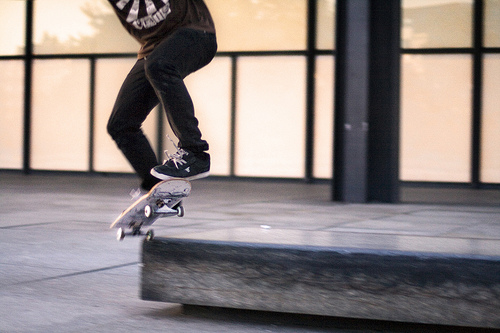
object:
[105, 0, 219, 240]
skateboarder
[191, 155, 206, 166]
black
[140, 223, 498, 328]
bench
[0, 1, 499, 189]
building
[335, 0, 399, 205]
pole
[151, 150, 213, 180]
foot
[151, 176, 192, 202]
front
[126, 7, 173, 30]
writing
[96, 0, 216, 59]
shirt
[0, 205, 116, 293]
ground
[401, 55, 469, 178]
pink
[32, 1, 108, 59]
trees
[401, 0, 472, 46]
reflection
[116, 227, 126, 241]
wheels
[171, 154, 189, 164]
white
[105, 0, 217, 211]
person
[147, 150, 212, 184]
wearing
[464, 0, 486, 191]
bar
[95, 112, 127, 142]
knees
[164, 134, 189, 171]
laces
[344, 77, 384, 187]
steel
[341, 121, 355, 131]
rivets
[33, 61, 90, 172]
windows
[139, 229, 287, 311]
step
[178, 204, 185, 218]
white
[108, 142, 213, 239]
skating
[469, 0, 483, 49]
frames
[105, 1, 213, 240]
trick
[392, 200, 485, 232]
concrete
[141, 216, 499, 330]
concrete